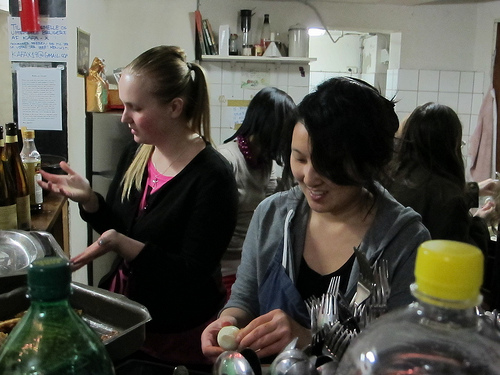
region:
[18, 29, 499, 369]
woman in a kitchen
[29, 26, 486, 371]
woman cooking the kitchen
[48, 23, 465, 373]
woman standing in the kitchen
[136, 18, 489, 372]
a woman peeling eggs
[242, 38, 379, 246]
a woman short black hair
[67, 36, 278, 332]
a woman with blonde hair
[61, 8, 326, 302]
a woman with a pony tail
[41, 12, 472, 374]
women standing inside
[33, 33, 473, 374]
women standing inside a building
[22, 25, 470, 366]
woman standing in a kitchen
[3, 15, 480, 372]
these ladies are working in a kitchen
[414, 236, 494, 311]
the bottle cap is yellow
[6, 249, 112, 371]
this bottle & cap are green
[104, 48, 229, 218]
this lady has her hair in a pony tail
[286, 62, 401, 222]
this lady appears to have short hair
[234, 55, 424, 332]
she is wearing a grey hoodie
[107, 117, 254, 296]
this lady is wearing a black sweater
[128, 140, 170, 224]
she also is dressed in a pink shirt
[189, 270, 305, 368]
this lady is peeling an egg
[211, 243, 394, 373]
forks & spoons are in the photo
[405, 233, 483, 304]
yellow bottle cap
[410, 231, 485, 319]
plastic bottle cap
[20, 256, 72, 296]
green bottle cap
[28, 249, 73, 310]
green plastic bottle cap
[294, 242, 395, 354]
metal forks in a container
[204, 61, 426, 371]
woman standing with sweatshirt on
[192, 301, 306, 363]
woman holding object in hands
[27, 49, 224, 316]
girl making a hand gesture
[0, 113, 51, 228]
bottles of liquid on table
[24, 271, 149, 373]
silver metal cooking trey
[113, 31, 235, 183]
girl's hair in pontail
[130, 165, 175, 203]
girl's shirt is pink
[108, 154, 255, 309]
girl's jacket is pink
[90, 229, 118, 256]
girl's nails are painted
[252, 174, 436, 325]
girl's jacket is gray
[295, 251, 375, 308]
girls shirt is black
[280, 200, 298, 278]
white draw string on jacket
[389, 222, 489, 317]
the top is yellow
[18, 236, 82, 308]
the top is green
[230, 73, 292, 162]
woman's hair is black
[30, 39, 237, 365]
A woman standing in the kitchen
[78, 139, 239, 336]
The woman has a black sweater on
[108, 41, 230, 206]
The woman has blonde hair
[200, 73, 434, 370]
The woman is smiling and peeling and egg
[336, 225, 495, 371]
A bottle with a yellow cap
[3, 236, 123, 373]
A green bottle with a green cap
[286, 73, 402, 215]
The woman has black hair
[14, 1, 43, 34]
The fire hydrant on the wall is red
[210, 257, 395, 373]
The silverware is clean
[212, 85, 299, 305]
The woman has on a gray sweater